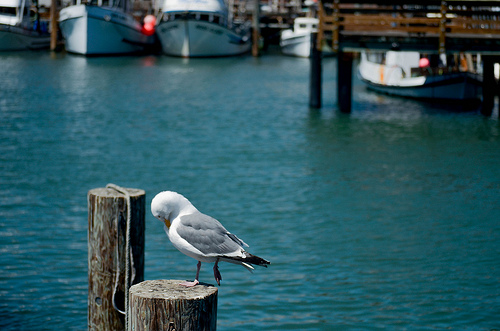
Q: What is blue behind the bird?
A: Water.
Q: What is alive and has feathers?
A: A bird.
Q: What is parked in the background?
A: Boats.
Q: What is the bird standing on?
A: The wooden pole.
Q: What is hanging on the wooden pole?
A: Rope.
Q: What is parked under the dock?
A: Boat.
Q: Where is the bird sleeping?
A: On the post.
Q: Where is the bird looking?
A: Down.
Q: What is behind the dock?
A: A boat.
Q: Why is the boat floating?
A: In water.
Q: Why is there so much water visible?
A: Empty of boats.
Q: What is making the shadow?
A: A boat.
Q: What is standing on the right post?
A: A bird.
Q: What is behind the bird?
A: Empty water.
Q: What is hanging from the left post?
A: A rope.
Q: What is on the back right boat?
A: Stripes.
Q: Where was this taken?
A: Beach.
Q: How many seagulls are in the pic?
A: One.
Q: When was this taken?
A: During the day.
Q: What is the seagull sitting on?
A: Wood.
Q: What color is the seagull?
A: Gray and white.